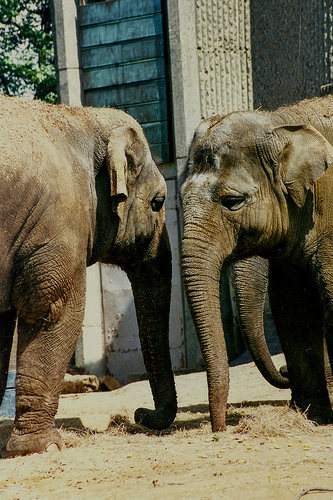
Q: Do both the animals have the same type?
A: Yes, all the animals are elephants.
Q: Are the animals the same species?
A: Yes, all the animals are elephants.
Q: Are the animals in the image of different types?
A: No, all the animals are elephants.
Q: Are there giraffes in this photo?
A: No, there are no giraffes.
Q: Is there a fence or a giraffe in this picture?
A: No, there are no giraffes or fences.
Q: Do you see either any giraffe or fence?
A: No, there are no giraffes or fences.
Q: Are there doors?
A: Yes, there is a door.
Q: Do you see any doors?
A: Yes, there is a door.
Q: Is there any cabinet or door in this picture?
A: Yes, there is a door.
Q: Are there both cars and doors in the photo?
A: No, there is a door but no cars.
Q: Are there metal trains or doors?
A: Yes, there is a metal door.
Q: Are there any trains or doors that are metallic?
A: Yes, the door is metallic.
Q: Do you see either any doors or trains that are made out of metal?
A: Yes, the door is made of metal.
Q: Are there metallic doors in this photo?
A: Yes, there is a metal door.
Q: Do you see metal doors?
A: Yes, there is a metal door.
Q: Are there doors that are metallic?
A: Yes, there is a door that is metallic.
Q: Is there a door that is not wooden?
A: Yes, there is a metallic door.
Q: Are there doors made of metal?
A: Yes, there is a door that is made of metal.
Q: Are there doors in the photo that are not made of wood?
A: Yes, there is a door that is made of metal.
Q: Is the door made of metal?
A: Yes, the door is made of metal.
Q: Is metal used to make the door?
A: Yes, the door is made of metal.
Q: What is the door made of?
A: The door is made of metal.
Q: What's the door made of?
A: The door is made of metal.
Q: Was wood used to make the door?
A: No, the door is made of metal.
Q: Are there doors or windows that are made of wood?
A: No, there is a door but it is made of metal.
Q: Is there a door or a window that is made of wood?
A: No, there is a door but it is made of metal.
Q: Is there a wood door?
A: No, there is a door but it is made of metal.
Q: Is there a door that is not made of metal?
A: No, there is a door but it is made of metal.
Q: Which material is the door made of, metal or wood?
A: The door is made of metal.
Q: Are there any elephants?
A: Yes, there is an elephant.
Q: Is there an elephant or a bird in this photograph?
A: Yes, there is an elephant.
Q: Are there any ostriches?
A: No, there are no ostriches.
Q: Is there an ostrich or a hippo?
A: No, there are no ostriches or hippos.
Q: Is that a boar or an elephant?
A: That is an elephant.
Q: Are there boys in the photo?
A: No, there are no boys.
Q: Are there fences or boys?
A: No, there are no boys or fences.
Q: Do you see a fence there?
A: No, there are no fences.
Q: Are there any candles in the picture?
A: No, there are no candles.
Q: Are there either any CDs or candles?
A: No, there are no candles or cds.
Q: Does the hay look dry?
A: Yes, the hay is dry.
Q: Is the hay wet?
A: No, the hay is dry.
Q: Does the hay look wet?
A: No, the hay is dry.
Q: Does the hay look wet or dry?
A: The hay is dry.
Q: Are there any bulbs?
A: No, there are no bulbs.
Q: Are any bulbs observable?
A: No, there are no bulbs.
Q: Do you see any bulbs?
A: No, there are no bulbs.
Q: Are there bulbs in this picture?
A: No, there are no bulbs.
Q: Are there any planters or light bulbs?
A: No, there are no light bulbs or planters.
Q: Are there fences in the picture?
A: No, there are no fences.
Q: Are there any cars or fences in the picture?
A: No, there are no fences or cars.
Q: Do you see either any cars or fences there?
A: No, there are no fences or cars.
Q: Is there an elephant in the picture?
A: Yes, there is an elephant.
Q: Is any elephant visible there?
A: Yes, there is an elephant.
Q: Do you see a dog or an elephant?
A: Yes, there is an elephant.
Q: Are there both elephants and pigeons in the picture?
A: No, there is an elephant but no pigeons.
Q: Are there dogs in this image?
A: No, there are no dogs.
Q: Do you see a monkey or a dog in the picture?
A: No, there are no dogs or monkeys.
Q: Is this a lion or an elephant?
A: This is an elephant.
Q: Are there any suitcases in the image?
A: No, there are no suitcases.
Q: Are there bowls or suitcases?
A: No, there are no suitcases or bowls.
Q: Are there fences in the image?
A: No, there are no fences.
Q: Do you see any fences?
A: No, there are no fences.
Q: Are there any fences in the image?
A: No, there are no fences.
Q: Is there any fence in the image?
A: No, there are no fences.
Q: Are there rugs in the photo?
A: No, there are no rugs.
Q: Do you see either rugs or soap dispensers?
A: No, there are no rugs or soap dispensers.